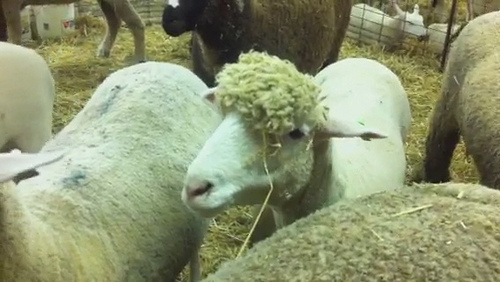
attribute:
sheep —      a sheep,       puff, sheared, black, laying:
[214, 63, 339, 143]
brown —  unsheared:
[227, 16, 326, 46]